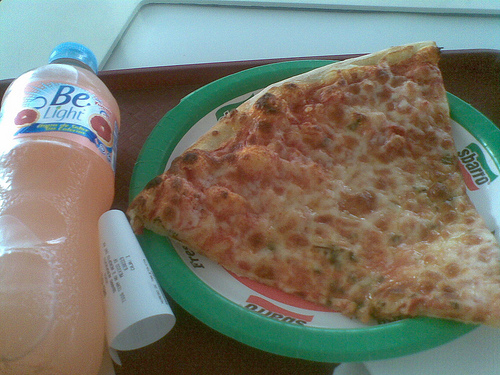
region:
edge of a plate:
[290, 339, 336, 357]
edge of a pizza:
[429, 282, 487, 317]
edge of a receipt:
[138, 310, 162, 332]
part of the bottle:
[42, 253, 100, 306]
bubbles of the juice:
[16, 251, 51, 306]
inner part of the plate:
[275, 295, 299, 329]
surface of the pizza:
[326, 172, 372, 219]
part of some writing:
[274, 294, 310, 312]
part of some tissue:
[471, 340, 485, 357]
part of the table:
[206, 342, 244, 362]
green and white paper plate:
[131, 59, 498, 354]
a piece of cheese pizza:
[130, 40, 498, 337]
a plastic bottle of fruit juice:
[1, 39, 119, 372]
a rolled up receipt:
[99, 208, 176, 365]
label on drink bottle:
[2, 84, 118, 167]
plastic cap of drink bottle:
[47, 42, 98, 67]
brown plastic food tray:
[0, 48, 498, 373]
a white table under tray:
[96, 1, 496, 76]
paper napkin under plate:
[331, 307, 497, 372]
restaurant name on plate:
[454, 141, 499, 196]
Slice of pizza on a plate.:
[160, 52, 493, 311]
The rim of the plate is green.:
[201, 289, 251, 341]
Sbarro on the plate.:
[460, 142, 494, 199]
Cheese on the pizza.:
[272, 160, 365, 215]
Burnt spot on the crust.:
[237, 77, 294, 117]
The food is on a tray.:
[4, 67, 498, 230]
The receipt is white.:
[91, 210, 167, 350]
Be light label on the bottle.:
[18, 70, 115, 149]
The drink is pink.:
[13, 162, 75, 242]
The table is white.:
[14, 9, 107, 36]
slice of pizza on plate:
[162, 35, 479, 319]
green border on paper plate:
[186, 268, 304, 348]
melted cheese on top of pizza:
[341, 178, 446, 255]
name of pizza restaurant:
[450, 118, 491, 196]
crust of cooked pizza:
[237, 54, 347, 121]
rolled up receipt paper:
[90, 201, 174, 351]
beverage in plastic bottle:
[5, 61, 120, 310]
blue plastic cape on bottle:
[44, 38, 105, 78]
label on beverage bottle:
[17, 77, 117, 159]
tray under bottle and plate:
[93, 45, 283, 124]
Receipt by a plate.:
[82, 182, 196, 373]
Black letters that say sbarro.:
[190, 284, 332, 356]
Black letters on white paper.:
[77, 216, 147, 303]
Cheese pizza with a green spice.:
[235, 178, 497, 325]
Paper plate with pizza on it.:
[166, 185, 455, 347]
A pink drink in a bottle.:
[6, 178, 99, 360]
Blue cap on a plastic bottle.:
[20, 18, 128, 83]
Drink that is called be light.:
[17, 97, 100, 247]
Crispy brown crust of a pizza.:
[137, 105, 274, 208]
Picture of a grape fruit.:
[40, 100, 145, 180]